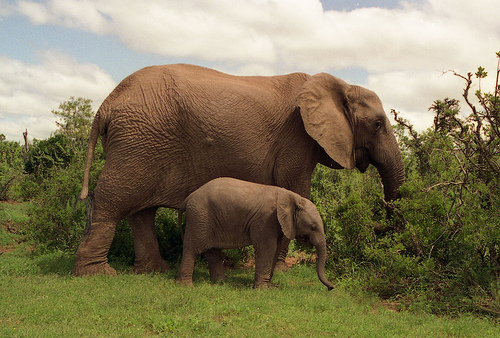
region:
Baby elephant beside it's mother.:
[181, 175, 329, 285]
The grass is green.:
[26, 274, 235, 326]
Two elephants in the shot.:
[60, 46, 429, 291]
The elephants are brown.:
[118, 55, 356, 274]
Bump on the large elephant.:
[186, 127, 230, 162]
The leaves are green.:
[380, 192, 499, 280]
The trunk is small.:
[308, 246, 344, 298]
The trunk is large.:
[366, 151, 410, 219]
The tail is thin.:
[70, 118, 99, 194]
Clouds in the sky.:
[133, 7, 460, 99]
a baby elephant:
[173, 174, 335, 293]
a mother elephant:
[75, 60, 408, 275]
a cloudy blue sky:
[0, 1, 498, 142]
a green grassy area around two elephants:
[4, 201, 496, 336]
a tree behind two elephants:
[61, 90, 98, 157]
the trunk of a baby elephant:
[310, 240, 335, 296]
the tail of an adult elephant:
[73, 100, 103, 207]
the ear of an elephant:
[297, 71, 367, 180]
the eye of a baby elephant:
[309, 216, 319, 233]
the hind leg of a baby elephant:
[174, 235, 200, 289]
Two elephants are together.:
[33, 47, 459, 307]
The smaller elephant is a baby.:
[150, 171, 368, 302]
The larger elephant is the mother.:
[35, 51, 425, 296]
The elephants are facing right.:
[55, 48, 442, 296]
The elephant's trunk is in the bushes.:
[342, 80, 495, 288]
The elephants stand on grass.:
[0, 271, 498, 336]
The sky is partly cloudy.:
[0, 1, 498, 73]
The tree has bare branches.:
[418, 62, 498, 226]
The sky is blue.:
[0, 15, 133, 82]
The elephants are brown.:
[49, 50, 461, 305]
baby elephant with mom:
[123, 187, 340, 314]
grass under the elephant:
[263, 295, 362, 331]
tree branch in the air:
[451, 52, 487, 129]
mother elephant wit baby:
[26, 57, 429, 216]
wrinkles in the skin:
[116, 112, 178, 182]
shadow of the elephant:
[26, 246, 73, 311]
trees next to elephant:
[394, 82, 477, 184]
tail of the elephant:
[58, 127, 105, 239]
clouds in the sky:
[61, 64, 111, 94]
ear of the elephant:
[288, 70, 361, 195]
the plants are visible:
[430, 105, 496, 276]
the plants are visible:
[454, 50, 481, 300]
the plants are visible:
[380, 116, 431, 286]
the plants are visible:
[441, 122, 466, 320]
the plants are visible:
[410, 82, 483, 332]